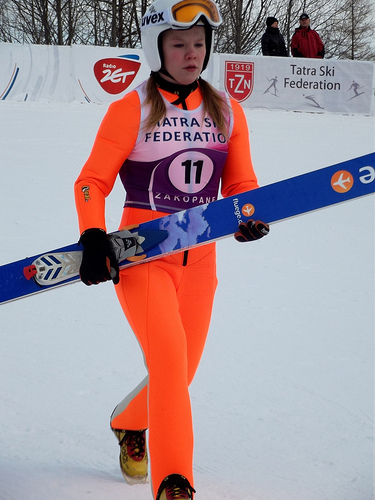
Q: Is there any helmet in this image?
A: Yes, there is a helmet.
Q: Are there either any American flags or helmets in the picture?
A: Yes, there is a helmet.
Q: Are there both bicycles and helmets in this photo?
A: No, there is a helmet but no bicycles.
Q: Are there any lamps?
A: No, there are no lamps.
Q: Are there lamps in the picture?
A: No, there are no lamps.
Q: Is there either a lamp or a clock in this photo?
A: No, there are no lamps or clocks.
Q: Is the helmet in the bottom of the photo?
A: No, the helmet is in the top of the image.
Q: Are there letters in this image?
A: Yes, there are letters.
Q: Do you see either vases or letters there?
A: Yes, there are letters.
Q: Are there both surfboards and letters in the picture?
A: No, there are letters but no surfboards.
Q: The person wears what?
A: The person wears a shirt.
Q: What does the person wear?
A: The person wears a shirt.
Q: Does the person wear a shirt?
A: Yes, the person wears a shirt.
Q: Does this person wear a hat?
A: No, the person wears a shirt.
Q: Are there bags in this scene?
A: No, there are no bags.